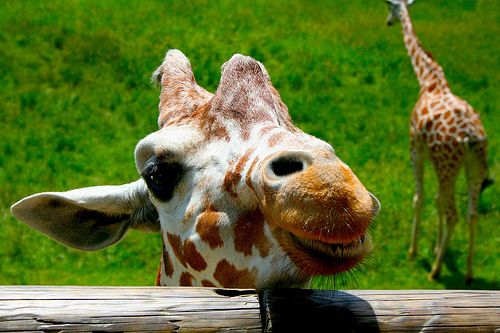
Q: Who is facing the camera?
A: The giraffe.